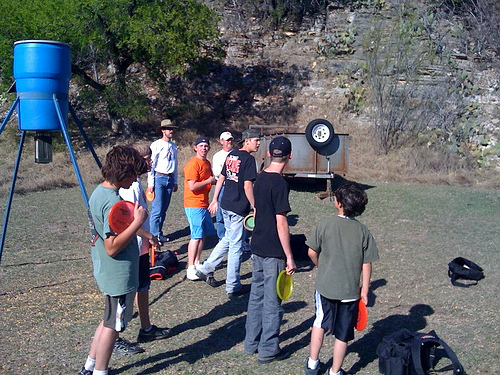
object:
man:
[147, 119, 178, 245]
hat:
[157, 119, 179, 132]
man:
[183, 138, 216, 280]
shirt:
[182, 156, 213, 208]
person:
[77, 144, 162, 374]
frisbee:
[109, 200, 135, 234]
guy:
[243, 136, 299, 364]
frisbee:
[276, 270, 292, 301]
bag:
[149, 250, 178, 280]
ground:
[0, 188, 497, 373]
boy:
[304, 185, 380, 375]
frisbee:
[356, 299, 367, 331]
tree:
[0, 1, 223, 135]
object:
[1, 38, 101, 259]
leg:
[51, 95, 89, 209]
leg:
[67, 102, 102, 168]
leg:
[0, 130, 26, 264]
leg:
[0, 97, 18, 134]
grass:
[1, 183, 498, 375]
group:
[82, 176, 380, 372]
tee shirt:
[305, 216, 379, 300]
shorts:
[313, 291, 359, 342]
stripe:
[313, 291, 325, 328]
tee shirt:
[251, 170, 293, 261]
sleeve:
[272, 174, 291, 216]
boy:
[196, 127, 260, 297]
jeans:
[201, 209, 245, 293]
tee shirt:
[221, 149, 258, 217]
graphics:
[224, 154, 241, 183]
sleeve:
[184, 158, 200, 183]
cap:
[194, 137, 209, 145]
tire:
[305, 118, 335, 148]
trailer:
[248, 118, 349, 202]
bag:
[448, 257, 484, 288]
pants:
[243, 253, 287, 361]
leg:
[244, 255, 265, 352]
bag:
[376, 328, 466, 375]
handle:
[411, 330, 464, 374]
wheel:
[314, 128, 326, 140]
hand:
[285, 261, 297, 275]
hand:
[361, 289, 368, 305]